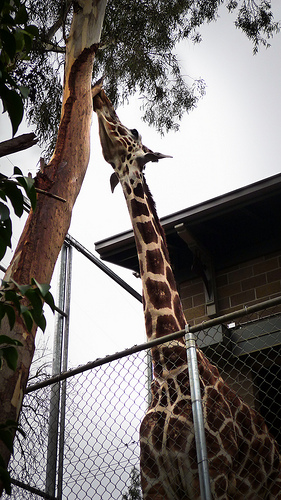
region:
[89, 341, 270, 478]
the giraffe has stripes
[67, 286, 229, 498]
the giraffe has stripes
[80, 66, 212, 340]
The giraffe reaches for food on the tree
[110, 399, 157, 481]
The fence is a chain link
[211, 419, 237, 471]
Giraffe has brown and white spots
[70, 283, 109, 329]
The sky is gray and cloudy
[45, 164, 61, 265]
Bark is coming off the tree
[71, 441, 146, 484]
Power lines stretch across the sky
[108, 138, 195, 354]
The giraffe stretches its neck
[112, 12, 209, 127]
The leaves are hanging from the tree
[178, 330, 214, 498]
The fence has a metal post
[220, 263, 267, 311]
The wall is brick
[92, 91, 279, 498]
a giraffe secured in a wire fence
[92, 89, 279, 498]
a brown spotted giraffe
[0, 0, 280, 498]
a giraffe at the zoo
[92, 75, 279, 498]
a giraffe touching the broken branch with the mouth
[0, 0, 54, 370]
green leaves on the branches of the tree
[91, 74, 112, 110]
a giraffe's mouth against the broken branch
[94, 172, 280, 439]
the edge of the facility for the giraffe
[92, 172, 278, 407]
the side of a brick building behind the giraffe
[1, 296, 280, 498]
wire metal fence surrounding the giraffe's habitat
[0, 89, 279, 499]
a giraffe standing under the tree branches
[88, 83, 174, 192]
the head of a giraffe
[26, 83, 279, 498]
a giraffe eating behind a chain link fence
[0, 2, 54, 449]
the leaves of a tree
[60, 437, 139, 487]
powerlines behind a chain link fence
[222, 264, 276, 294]
bricks on a building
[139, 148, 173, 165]
the ear of a giraffe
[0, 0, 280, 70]
the top of a large tree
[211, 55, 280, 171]
an overcast sky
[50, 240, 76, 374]
metal poles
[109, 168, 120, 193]
the ear of a giraffe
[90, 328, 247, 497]
the giraffe has stripes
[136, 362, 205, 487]
the giraffe has stripes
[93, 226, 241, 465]
the giraffe has stripes